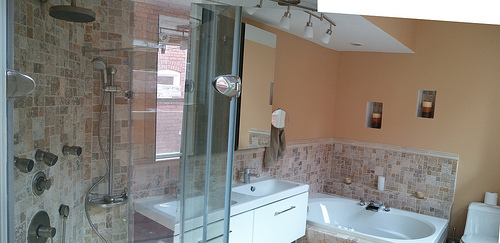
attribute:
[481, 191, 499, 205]
toilet paper — white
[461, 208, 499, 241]
toilet — white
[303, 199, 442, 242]
bath tub — large, white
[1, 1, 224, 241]
shower — glass, clear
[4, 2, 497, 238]
bathroom — peach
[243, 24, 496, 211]
wall — brown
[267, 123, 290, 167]
towel — brown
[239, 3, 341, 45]
lights — white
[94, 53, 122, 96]
shower head — metal, silver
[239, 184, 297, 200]
sink — white, porcelein, large